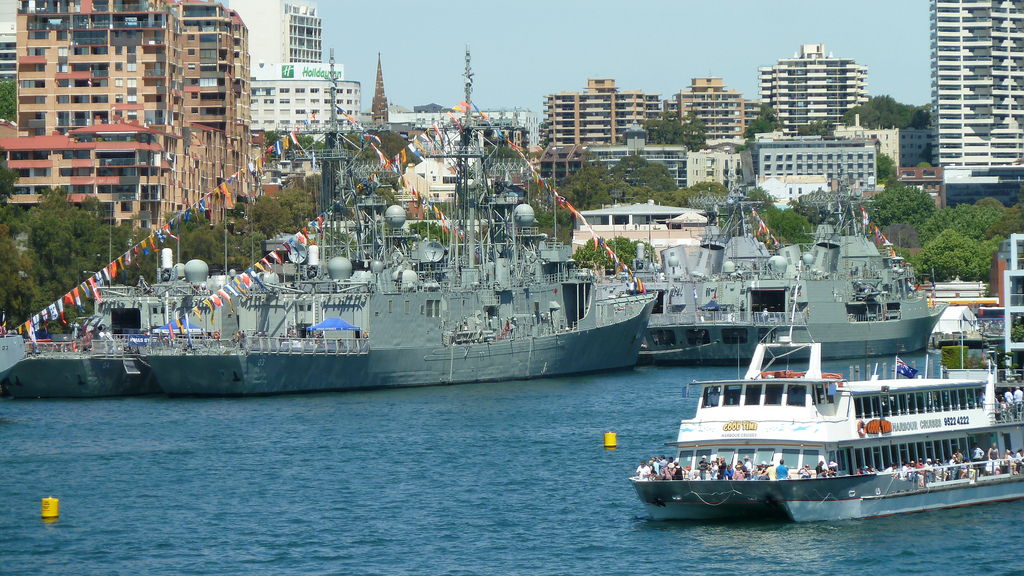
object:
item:
[41, 496, 58, 518]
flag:
[896, 356, 918, 379]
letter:
[944, 416, 971, 426]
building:
[929, 0, 1024, 207]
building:
[0, 0, 255, 237]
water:
[0, 350, 1024, 576]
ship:
[640, 203, 939, 370]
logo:
[857, 418, 892, 436]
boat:
[625, 338, 1024, 526]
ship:
[139, 44, 662, 397]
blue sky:
[323, 0, 934, 117]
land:
[0, 155, 1024, 331]